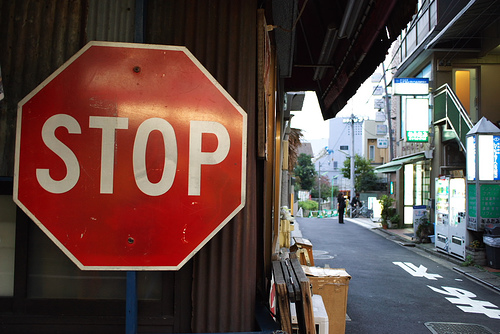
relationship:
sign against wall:
[11, 39, 250, 277] [0, 1, 262, 334]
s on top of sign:
[34, 113, 82, 197] [11, 39, 250, 277]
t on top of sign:
[86, 115, 130, 195] [11, 39, 250, 277]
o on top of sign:
[131, 114, 179, 200] [11, 39, 250, 277]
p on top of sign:
[183, 119, 232, 197] [11, 39, 250, 277]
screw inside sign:
[126, 236, 136, 246] [11, 39, 250, 277]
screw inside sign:
[131, 64, 142, 75] [11, 39, 250, 277]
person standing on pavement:
[336, 189, 350, 226] [286, 214, 499, 334]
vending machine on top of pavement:
[431, 173, 454, 259] [286, 214, 499, 334]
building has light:
[375, 0, 499, 235] [400, 159, 426, 231]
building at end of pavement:
[325, 114, 366, 200] [286, 214, 499, 334]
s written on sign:
[34, 113, 82, 197] [11, 39, 250, 277]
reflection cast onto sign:
[115, 98, 243, 137] [11, 39, 250, 277]